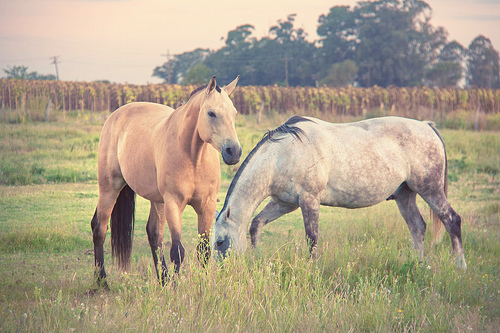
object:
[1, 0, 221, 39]
sky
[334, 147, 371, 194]
specks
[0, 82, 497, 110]
corn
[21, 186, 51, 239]
grass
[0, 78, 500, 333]
meadow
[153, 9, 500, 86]
trees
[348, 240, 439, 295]
grass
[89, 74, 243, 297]
horse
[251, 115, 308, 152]
mane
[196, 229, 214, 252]
flowers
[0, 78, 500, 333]
field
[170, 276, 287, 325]
grass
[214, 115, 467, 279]
greyhorse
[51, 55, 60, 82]
pole